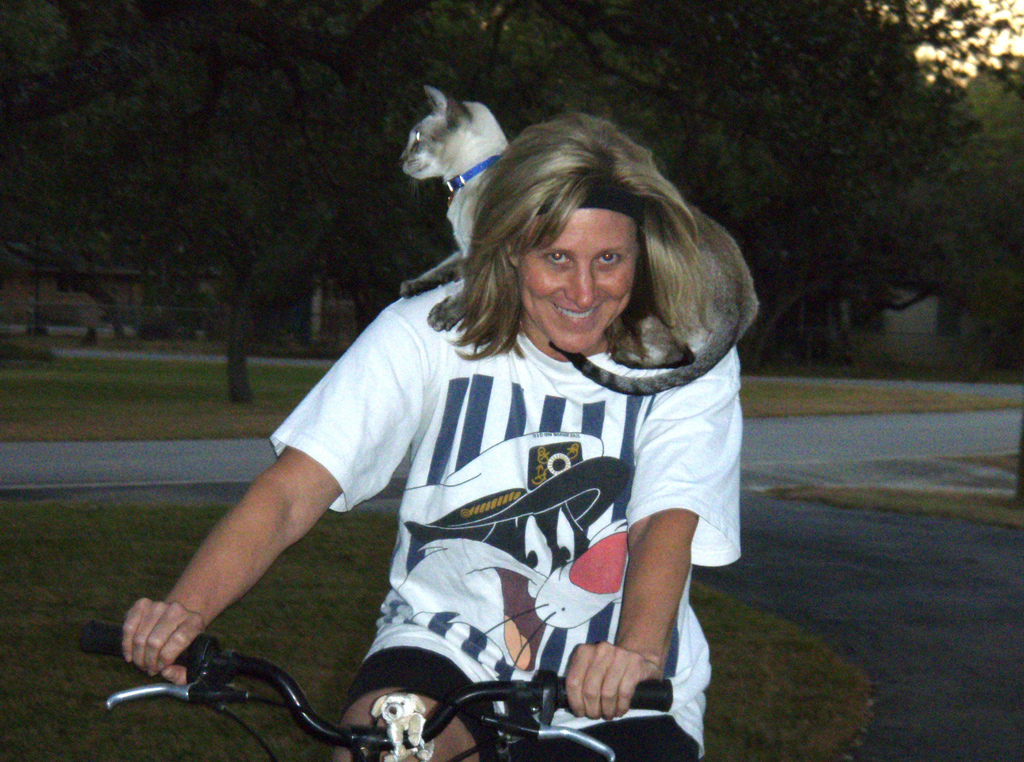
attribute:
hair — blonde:
[616, 180, 738, 368]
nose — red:
[561, 521, 648, 599]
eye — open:
[410, 126, 426, 144]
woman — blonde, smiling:
[114, 107, 747, 758]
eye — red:
[594, 247, 621, 265]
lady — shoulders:
[159, 107, 795, 753]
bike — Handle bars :
[116, 592, 566, 757]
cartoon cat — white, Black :
[445, 461, 631, 630]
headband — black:
[537, 173, 658, 217]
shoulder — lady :
[384, 279, 758, 401]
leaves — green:
[819, 50, 880, 109]